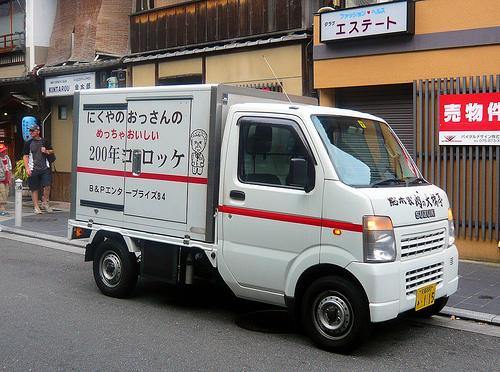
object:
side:
[214, 102, 376, 354]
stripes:
[77, 166, 207, 185]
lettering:
[487, 101, 500, 121]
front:
[207, 89, 460, 355]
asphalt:
[0, 232, 500, 372]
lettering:
[444, 104, 461, 122]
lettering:
[463, 103, 483, 122]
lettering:
[339, 6, 385, 19]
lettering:
[336, 15, 398, 36]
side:
[66, 84, 222, 263]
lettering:
[171, 147, 185, 168]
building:
[311, 0, 500, 263]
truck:
[67, 84, 459, 352]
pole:
[14, 178, 23, 227]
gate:
[331, 85, 420, 167]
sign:
[321, 3, 407, 40]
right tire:
[300, 276, 371, 356]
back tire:
[93, 239, 140, 299]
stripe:
[216, 205, 363, 234]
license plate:
[414, 284, 435, 311]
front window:
[237, 120, 317, 191]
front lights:
[363, 216, 393, 231]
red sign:
[434, 92, 500, 146]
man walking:
[22, 124, 57, 214]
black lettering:
[86, 109, 183, 125]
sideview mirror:
[288, 158, 307, 186]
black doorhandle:
[230, 190, 245, 201]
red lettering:
[96, 128, 159, 140]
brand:
[415, 209, 435, 219]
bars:
[49, 0, 313, 202]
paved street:
[0, 155, 500, 372]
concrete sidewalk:
[0, 190, 500, 327]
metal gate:
[414, 77, 500, 239]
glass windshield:
[306, 112, 426, 187]